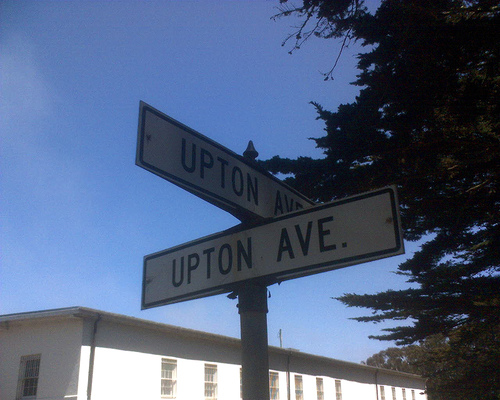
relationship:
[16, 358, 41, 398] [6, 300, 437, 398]
window on side of building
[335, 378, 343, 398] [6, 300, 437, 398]
window on side of building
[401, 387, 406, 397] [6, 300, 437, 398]
window on side of building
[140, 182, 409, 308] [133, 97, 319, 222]
sign on bottom of sign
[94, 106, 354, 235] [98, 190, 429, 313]
sign on top of sign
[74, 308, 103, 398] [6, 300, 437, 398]
gutter drain going down building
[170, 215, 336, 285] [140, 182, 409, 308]
words written on sign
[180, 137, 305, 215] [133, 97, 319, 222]
words written on sign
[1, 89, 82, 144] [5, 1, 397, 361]
clouds in sky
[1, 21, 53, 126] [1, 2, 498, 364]
clouds in sky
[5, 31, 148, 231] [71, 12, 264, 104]
clouds in sky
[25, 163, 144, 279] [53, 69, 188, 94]
clouds in sky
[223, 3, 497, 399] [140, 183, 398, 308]
trees on side of sign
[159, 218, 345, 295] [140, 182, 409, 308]
upton ave written on sign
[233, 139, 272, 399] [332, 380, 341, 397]
pole standing in front of window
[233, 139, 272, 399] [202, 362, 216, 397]
pole standing in front of window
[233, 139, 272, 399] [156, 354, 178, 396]
pole standing in front of window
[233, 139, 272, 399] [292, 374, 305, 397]
pole standing in front of window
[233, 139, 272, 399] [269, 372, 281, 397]
pole standing in front of window